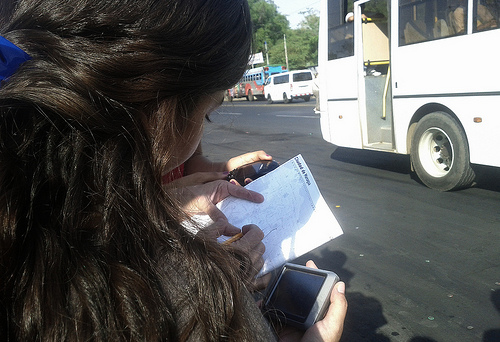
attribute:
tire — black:
[408, 110, 479, 192]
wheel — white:
[316, 0, 498, 192]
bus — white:
[296, 0, 497, 194]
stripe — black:
[327, 90, 499, 101]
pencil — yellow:
[220, 230, 249, 245]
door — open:
[355, 3, 412, 156]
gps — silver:
[263, 258, 334, 338]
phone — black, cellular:
[198, 157, 323, 187]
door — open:
[352, 1, 399, 150]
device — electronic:
[257, 255, 341, 332]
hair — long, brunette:
[45, 110, 167, 301]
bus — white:
[312, 5, 498, 187]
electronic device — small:
[259, 263, 348, 335]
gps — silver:
[259, 263, 339, 332]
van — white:
[260, 67, 315, 103]